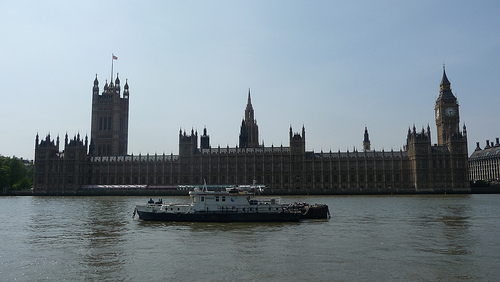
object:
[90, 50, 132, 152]
tower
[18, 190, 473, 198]
road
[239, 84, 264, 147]
steeple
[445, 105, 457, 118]
clock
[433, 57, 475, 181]
tower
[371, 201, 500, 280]
water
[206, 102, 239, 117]
white clouds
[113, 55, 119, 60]
flag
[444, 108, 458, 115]
face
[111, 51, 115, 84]
pole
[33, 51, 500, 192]
building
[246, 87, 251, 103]
spire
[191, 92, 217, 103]
cloud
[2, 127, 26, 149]
cloud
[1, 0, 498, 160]
sky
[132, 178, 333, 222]
boat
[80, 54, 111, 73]
white clouds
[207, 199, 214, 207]
white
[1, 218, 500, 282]
river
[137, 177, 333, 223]
profile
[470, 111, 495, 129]
cloud